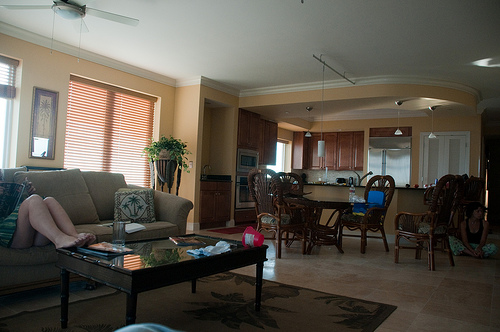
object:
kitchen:
[235, 109, 417, 214]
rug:
[0, 268, 399, 330]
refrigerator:
[366, 137, 411, 188]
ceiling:
[242, 39, 482, 127]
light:
[428, 106, 438, 139]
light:
[393, 100, 402, 135]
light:
[304, 105, 312, 137]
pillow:
[113, 185, 156, 223]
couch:
[0, 170, 194, 298]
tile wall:
[210, 142, 232, 169]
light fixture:
[318, 64, 326, 157]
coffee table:
[54, 232, 268, 328]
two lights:
[392, 99, 436, 139]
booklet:
[169, 236, 206, 245]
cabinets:
[215, 191, 231, 227]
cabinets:
[265, 120, 278, 165]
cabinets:
[353, 130, 364, 171]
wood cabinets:
[308, 133, 324, 170]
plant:
[143, 136, 193, 171]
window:
[65, 78, 156, 189]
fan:
[0, 2, 147, 57]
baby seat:
[350, 189, 386, 217]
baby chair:
[332, 173, 396, 255]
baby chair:
[251, 168, 314, 256]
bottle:
[348, 184, 355, 202]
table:
[275, 195, 365, 254]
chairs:
[393, 173, 462, 271]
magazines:
[79, 241, 135, 256]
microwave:
[238, 147, 259, 174]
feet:
[54, 236, 84, 250]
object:
[242, 225, 265, 247]